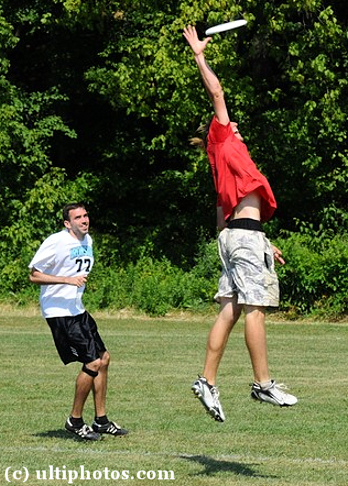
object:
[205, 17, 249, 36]
frisbee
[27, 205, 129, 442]
man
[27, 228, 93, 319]
t shirt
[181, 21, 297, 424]
man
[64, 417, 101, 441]
sneaker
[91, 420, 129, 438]
sneaker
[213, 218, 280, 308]
shorts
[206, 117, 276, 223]
t shirt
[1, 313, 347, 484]
field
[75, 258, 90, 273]
number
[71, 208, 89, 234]
face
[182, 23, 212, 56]
hand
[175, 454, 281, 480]
shadow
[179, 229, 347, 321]
bush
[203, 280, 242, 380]
leg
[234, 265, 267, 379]
leg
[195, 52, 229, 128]
arm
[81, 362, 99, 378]
band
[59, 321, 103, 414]
leg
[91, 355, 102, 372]
knee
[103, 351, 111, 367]
knee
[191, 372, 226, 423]
shoe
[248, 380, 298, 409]
shoe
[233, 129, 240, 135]
mouth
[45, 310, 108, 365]
shorts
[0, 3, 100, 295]
trees